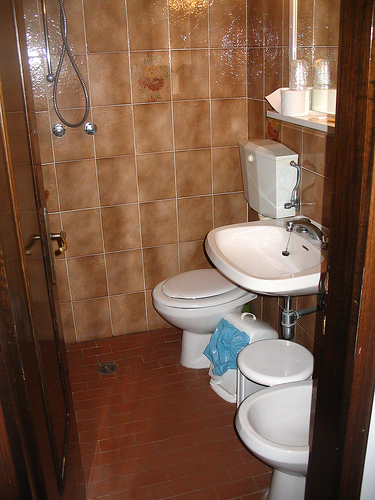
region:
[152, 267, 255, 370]
a closed white toilet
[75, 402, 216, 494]
a brown tile floor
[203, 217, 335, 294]
a white washbasin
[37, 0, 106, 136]
silver shower faucet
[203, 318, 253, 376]
a green pasltic bag in the trash can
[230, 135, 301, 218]
a rectangular toilet cistern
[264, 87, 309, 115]
a roll of white paper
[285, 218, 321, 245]
the washbasin faucet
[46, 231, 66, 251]
the handle of the door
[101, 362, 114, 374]
the plughole drain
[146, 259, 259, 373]
shiny white porcelain toilet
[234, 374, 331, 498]
shiny white porcelain bidet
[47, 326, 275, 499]
smooth red brick floor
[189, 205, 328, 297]
small white porcelain sink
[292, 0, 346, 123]
clean shiny mirror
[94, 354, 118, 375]
small brass drain in the floor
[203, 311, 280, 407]
small white plastic waste basket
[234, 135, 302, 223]
elevated white toilet tank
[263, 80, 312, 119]
roll of white toilet paper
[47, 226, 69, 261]
brass door handle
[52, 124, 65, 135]
Hot water knob on a shower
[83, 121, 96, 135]
Cold water knob on a shower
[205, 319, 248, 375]
A trash can bag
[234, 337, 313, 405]
Equipment used in a bathroom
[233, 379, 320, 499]
A bathroom toilet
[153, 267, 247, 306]
A toilet seat lid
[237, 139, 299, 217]
The flushing system on a toilet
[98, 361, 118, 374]
The drain in a shower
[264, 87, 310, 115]
A toilet paper roll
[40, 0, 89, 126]
A shower hose and head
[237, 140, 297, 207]
Tank on toilet is white.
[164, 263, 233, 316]
Seat on toilet is white.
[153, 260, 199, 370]
Toilet is white in color.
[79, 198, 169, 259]
Brown square tiles on wall in bathroom.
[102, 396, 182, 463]
Reddish brown tiles on floor.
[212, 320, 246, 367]
Blue bag in garbage can.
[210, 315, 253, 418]
White garbage can sitting on floor.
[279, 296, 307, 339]
Silver pipes under sink.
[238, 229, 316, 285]
White sink attached to wall.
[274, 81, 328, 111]
Extra rolls of toilet paper on shelf.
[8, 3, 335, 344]
bathroom walls covered in glossy brown tiles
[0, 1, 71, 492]
wooden door and handle on side of wall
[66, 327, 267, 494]
brick tiles covering floor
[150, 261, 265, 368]
closed white toilet in corner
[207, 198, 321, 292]
square white sink against wall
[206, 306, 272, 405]
folded plastic bag in front of white container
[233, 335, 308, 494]
round white container next to white bidet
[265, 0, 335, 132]
tray under mirror holding plastic cups and toilet paper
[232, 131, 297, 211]
white toilet tank against wall with metal pipe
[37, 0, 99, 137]
twisted loop near metal rod and round knobs